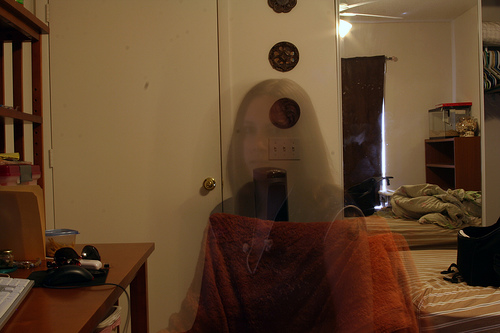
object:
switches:
[265, 139, 304, 162]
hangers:
[483, 48, 498, 90]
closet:
[481, 1, 498, 229]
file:
[3, 184, 50, 270]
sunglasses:
[54, 237, 100, 265]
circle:
[268, 97, 302, 130]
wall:
[222, 0, 336, 215]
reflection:
[173, 77, 376, 332]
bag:
[455, 218, 499, 289]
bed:
[386, 247, 498, 331]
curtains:
[337, 55, 412, 220]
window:
[376, 99, 390, 189]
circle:
[267, 40, 301, 73]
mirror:
[216, 1, 498, 240]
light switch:
[268, 136, 301, 160]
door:
[49, 3, 221, 326]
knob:
[203, 176, 216, 191]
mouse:
[26, 263, 97, 293]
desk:
[1, 2, 158, 332]